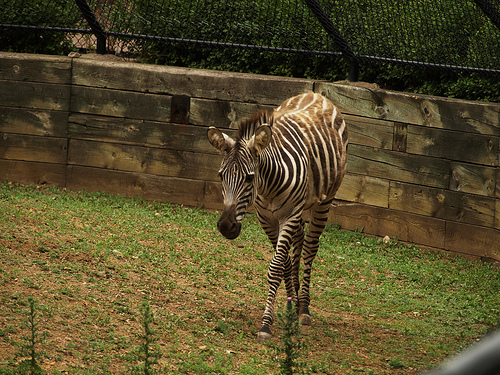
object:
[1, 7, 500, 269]
building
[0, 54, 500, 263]
wall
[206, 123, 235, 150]
ears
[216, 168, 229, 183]
eyes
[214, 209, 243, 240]
snout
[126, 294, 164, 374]
trees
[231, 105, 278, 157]
mane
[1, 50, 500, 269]
fence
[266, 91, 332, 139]
back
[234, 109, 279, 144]
hairs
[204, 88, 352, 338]
zebra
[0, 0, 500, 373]
enclosure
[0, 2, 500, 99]
fence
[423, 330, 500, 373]
railing part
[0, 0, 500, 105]
trees/bushes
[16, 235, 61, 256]
patches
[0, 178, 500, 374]
field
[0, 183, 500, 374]
bottom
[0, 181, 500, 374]
hill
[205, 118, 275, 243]
zebra head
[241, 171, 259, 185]
zebra eyes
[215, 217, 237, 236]
zebra nose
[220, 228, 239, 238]
zebra mouth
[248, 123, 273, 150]
zebra ear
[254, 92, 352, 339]
zebra body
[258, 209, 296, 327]
zebra leg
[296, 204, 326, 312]
zebra leg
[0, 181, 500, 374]
grass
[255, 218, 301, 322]
leg